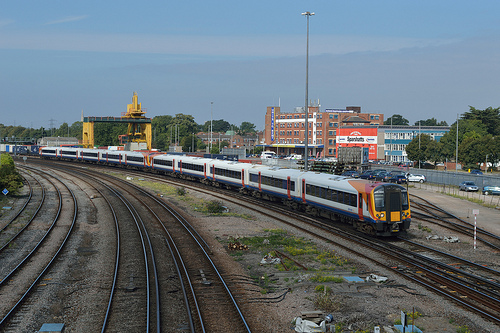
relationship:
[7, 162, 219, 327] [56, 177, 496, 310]
tracks on ground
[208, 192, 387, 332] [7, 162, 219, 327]
land between tracks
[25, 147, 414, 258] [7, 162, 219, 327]
train on tracks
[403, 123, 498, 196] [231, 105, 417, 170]
trees near buildings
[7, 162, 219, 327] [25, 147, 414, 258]
tracks near train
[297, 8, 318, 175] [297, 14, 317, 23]
post has light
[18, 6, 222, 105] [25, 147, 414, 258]
sky above train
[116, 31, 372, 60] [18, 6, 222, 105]
clouds in sky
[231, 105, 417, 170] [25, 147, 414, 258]
buildings behind train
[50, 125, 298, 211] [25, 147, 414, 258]
cars on train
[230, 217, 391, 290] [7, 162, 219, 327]
litter between tracks